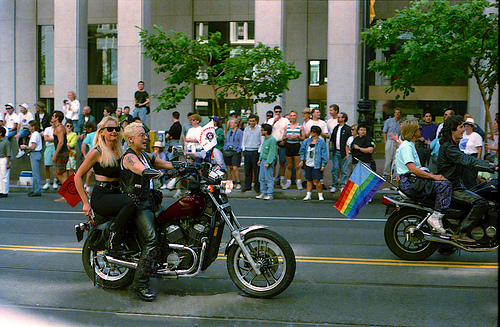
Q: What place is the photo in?
A: It is at the road.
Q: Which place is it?
A: It is a road.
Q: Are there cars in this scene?
A: No, there are no cars.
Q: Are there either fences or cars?
A: No, there are no cars or fences.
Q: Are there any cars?
A: No, there are no cars.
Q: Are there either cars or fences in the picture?
A: No, there are no cars or fences.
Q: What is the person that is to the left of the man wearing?
A: The person is wearing a jacket.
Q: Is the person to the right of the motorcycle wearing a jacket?
A: Yes, the person is wearing a jacket.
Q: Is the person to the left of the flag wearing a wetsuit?
A: No, the person is wearing a jacket.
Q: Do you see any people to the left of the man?
A: Yes, there is a person to the left of the man.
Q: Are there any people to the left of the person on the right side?
A: Yes, there is a person to the left of the man.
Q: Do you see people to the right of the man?
A: No, the person is to the left of the man.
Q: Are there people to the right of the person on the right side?
A: No, the person is to the left of the man.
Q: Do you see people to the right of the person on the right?
A: No, the person is to the left of the man.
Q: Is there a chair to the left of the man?
A: No, there is a person to the left of the man.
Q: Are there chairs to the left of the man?
A: No, there is a person to the left of the man.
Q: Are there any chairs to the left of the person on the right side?
A: No, there is a person to the left of the man.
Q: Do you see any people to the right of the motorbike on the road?
A: Yes, there is a person to the right of the motorbike.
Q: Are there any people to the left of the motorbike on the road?
A: No, the person is to the right of the motorcycle.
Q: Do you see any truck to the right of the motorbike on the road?
A: No, there is a person to the right of the motorcycle.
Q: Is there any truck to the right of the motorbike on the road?
A: No, there is a person to the right of the motorcycle.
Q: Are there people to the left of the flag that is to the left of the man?
A: Yes, there is a person to the left of the flag.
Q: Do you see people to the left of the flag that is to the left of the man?
A: Yes, there is a person to the left of the flag.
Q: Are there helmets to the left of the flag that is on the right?
A: No, there is a person to the left of the flag.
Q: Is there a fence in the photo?
A: No, there are no fences.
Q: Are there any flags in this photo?
A: Yes, there is a flag.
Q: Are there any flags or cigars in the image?
A: Yes, there is a flag.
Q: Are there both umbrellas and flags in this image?
A: No, there is a flag but no umbrellas.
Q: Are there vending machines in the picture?
A: No, there are no vending machines.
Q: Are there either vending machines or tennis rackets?
A: No, there are no vending machines or tennis rackets.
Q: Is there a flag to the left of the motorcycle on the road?
A: Yes, there is a flag to the left of the motorcycle.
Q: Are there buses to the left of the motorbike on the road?
A: No, there is a flag to the left of the motorbike.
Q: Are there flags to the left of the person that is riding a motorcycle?
A: Yes, there is a flag to the left of the person.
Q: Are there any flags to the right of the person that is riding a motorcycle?
A: No, the flag is to the left of the person.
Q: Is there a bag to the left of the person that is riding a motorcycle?
A: No, there is a flag to the left of the person.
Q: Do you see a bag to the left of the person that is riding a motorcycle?
A: No, there is a flag to the left of the person.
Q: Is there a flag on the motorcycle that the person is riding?
A: Yes, there is a flag on the motorcycle.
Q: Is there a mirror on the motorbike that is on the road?
A: No, there is a flag on the motorcycle.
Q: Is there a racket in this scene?
A: No, there are no rackets.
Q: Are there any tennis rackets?
A: No, there are no tennis rackets.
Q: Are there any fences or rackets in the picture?
A: No, there are no rackets or fences.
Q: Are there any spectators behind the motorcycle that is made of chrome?
A: Yes, there are spectators behind the motorbike.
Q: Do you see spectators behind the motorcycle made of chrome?
A: Yes, there are spectators behind the motorbike.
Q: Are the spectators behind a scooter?
A: No, the spectators are behind a motorcycle.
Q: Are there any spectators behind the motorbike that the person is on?
A: Yes, there are spectators behind the motorcycle.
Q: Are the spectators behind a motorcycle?
A: Yes, the spectators are behind a motorcycle.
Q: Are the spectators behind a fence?
A: No, the spectators are behind a motorcycle.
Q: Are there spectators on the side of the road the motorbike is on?
A: Yes, there are spectators on the side of the road.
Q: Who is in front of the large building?
A: The spectators are in front of the building.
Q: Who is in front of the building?
A: The spectators are in front of the building.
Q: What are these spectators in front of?
A: The spectators are in front of the building.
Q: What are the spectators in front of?
A: The spectators are in front of the building.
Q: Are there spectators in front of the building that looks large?
A: Yes, there are spectators in front of the building.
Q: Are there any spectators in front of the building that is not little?
A: Yes, there are spectators in front of the building.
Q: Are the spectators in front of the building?
A: Yes, the spectators are in front of the building.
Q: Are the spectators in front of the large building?
A: Yes, the spectators are in front of the building.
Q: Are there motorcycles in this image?
A: Yes, there is a motorcycle.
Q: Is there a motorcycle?
A: Yes, there is a motorcycle.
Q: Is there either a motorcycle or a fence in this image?
A: Yes, there is a motorcycle.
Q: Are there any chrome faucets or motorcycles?
A: Yes, there is a chrome motorcycle.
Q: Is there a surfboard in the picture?
A: No, there are no surfboards.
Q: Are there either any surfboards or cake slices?
A: No, there are no surfboards or cake slices.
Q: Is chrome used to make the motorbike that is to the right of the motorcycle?
A: Yes, the motorbike is made of chrome.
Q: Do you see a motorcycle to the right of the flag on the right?
A: Yes, there is a motorcycle to the right of the flag.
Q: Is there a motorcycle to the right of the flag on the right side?
A: Yes, there is a motorcycle to the right of the flag.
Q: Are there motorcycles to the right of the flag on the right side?
A: Yes, there is a motorcycle to the right of the flag.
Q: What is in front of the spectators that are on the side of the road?
A: The motorbike is in front of the spectators.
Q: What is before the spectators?
A: The motorbike is in front of the spectators.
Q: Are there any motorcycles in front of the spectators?
A: Yes, there is a motorcycle in front of the spectators.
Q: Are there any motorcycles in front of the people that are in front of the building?
A: Yes, there is a motorcycle in front of the spectators.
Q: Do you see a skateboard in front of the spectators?
A: No, there is a motorcycle in front of the spectators.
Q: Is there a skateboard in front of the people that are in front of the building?
A: No, there is a motorcycle in front of the spectators.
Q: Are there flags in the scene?
A: Yes, there is a flag.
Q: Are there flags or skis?
A: Yes, there is a flag.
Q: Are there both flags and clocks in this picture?
A: No, there is a flag but no clocks.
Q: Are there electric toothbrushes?
A: No, there are no electric toothbrushes.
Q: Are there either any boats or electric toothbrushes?
A: No, there are no electric toothbrushes or boats.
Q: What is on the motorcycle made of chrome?
A: The flag is on the motorcycle.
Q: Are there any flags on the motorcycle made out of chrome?
A: Yes, there is a flag on the motorcycle.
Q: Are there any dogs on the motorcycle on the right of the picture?
A: No, there is a flag on the motorcycle.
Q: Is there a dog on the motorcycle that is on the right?
A: No, there is a flag on the motorcycle.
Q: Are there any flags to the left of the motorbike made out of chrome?
A: Yes, there is a flag to the left of the motorcycle.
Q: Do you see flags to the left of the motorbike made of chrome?
A: Yes, there is a flag to the left of the motorcycle.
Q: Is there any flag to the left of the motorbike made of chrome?
A: Yes, there is a flag to the left of the motorcycle.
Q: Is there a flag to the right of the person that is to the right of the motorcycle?
A: Yes, there is a flag to the right of the person.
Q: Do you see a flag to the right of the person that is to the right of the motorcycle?
A: Yes, there is a flag to the right of the person.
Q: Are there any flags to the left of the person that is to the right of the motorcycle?
A: No, the flag is to the right of the person.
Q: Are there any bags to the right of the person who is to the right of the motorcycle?
A: No, there is a flag to the right of the person.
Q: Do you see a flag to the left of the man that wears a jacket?
A: Yes, there is a flag to the left of the man.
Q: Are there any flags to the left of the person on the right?
A: Yes, there is a flag to the left of the man.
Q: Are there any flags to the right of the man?
A: No, the flag is to the left of the man.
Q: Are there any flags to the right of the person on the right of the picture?
A: No, the flag is to the left of the man.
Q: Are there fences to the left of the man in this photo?
A: No, there is a flag to the left of the man.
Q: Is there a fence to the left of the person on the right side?
A: No, there is a flag to the left of the man.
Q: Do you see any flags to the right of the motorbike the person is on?
A: Yes, there is a flag to the right of the motorcycle.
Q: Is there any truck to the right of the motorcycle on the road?
A: No, there is a flag to the right of the motorbike.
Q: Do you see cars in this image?
A: No, there are no cars.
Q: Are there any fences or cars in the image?
A: No, there are no cars or fences.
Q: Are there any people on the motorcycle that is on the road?
A: Yes, there is a person on the motorcycle.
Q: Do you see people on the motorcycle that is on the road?
A: Yes, there is a person on the motorcycle.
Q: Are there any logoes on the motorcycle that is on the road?
A: No, there is a person on the motorbike.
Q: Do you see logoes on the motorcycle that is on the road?
A: No, there is a person on the motorbike.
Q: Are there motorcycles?
A: Yes, there is a motorcycle.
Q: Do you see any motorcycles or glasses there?
A: Yes, there is a motorcycle.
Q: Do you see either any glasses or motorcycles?
A: Yes, there is a motorcycle.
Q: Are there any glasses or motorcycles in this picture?
A: Yes, there is a motorcycle.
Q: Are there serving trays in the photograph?
A: No, there are no serving trays.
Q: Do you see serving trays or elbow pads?
A: No, there are no serving trays or elbow pads.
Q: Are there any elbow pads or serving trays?
A: No, there are no serving trays or elbow pads.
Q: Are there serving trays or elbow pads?
A: No, there are no serving trays or elbow pads.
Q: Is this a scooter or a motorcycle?
A: This is a motorcycle.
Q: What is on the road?
A: The motorbike is on the road.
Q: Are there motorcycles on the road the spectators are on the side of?
A: Yes, there is a motorcycle on the road.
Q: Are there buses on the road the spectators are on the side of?
A: No, there is a motorcycle on the road.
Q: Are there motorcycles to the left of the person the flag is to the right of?
A: Yes, there is a motorcycle to the left of the person.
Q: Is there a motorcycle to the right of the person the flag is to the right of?
A: No, the motorcycle is to the left of the person.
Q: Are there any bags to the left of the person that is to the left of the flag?
A: No, there is a motorcycle to the left of the person.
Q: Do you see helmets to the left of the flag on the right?
A: No, there is a motorcycle to the left of the flag.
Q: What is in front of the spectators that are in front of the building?
A: The motorcycle is in front of the spectators.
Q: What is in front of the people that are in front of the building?
A: The motorcycle is in front of the spectators.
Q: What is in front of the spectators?
A: The motorcycle is in front of the spectators.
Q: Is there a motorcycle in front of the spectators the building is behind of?
A: Yes, there is a motorcycle in front of the spectators.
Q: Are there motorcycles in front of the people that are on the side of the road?
A: Yes, there is a motorcycle in front of the spectators.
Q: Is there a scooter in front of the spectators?
A: No, there is a motorcycle in front of the spectators.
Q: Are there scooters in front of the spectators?
A: No, there is a motorcycle in front of the spectators.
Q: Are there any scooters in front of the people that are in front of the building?
A: No, there is a motorcycle in front of the spectators.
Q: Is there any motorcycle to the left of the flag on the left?
A: No, the motorcycle is to the right of the flag.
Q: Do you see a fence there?
A: No, there are no fences.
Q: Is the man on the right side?
A: Yes, the man is on the right of the image.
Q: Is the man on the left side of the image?
A: No, the man is on the right of the image.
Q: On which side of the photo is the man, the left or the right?
A: The man is on the right of the image.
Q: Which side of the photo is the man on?
A: The man is on the right of the image.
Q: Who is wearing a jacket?
A: The man is wearing a jacket.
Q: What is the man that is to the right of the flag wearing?
A: The man is wearing a jacket.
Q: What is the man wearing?
A: The man is wearing a jacket.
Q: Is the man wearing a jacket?
A: Yes, the man is wearing a jacket.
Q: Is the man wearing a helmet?
A: No, the man is wearing a jacket.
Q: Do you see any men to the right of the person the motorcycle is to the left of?
A: Yes, there is a man to the right of the person.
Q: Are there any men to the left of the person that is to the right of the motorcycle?
A: No, the man is to the right of the person.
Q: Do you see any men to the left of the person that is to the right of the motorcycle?
A: No, the man is to the right of the person.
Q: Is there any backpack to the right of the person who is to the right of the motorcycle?
A: No, there is a man to the right of the person.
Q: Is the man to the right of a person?
A: Yes, the man is to the right of a person.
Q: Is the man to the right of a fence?
A: No, the man is to the right of a person.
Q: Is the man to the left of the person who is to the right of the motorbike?
A: No, the man is to the right of the person.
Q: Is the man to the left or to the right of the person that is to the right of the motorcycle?
A: The man is to the right of the person.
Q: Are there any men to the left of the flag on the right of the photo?
A: No, the man is to the right of the flag.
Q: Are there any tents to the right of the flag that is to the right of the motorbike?
A: No, there is a man to the right of the flag.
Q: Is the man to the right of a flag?
A: Yes, the man is to the right of a flag.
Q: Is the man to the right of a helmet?
A: No, the man is to the right of a flag.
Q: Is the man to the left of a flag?
A: No, the man is to the right of a flag.